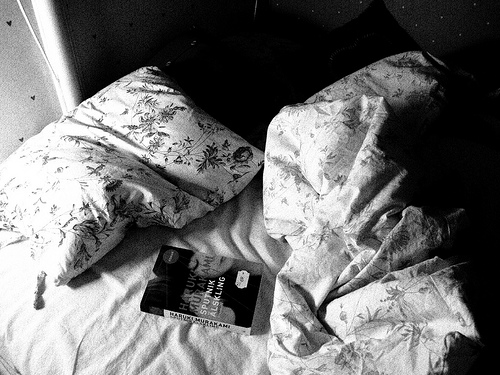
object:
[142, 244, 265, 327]
side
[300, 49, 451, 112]
pillow cover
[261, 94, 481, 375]
sheet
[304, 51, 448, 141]
pillow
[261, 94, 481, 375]
cloth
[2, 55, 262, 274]
pillowcase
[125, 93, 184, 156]
design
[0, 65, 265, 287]
pillow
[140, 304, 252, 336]
edge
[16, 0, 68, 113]
cord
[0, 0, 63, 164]
blind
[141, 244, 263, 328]
image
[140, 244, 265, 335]
bird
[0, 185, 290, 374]
sheet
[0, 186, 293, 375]
fitted sheet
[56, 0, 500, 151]
window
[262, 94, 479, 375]
comforter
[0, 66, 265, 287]
pillow case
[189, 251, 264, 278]
woman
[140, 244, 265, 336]
book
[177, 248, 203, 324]
part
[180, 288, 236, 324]
man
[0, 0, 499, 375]
bed